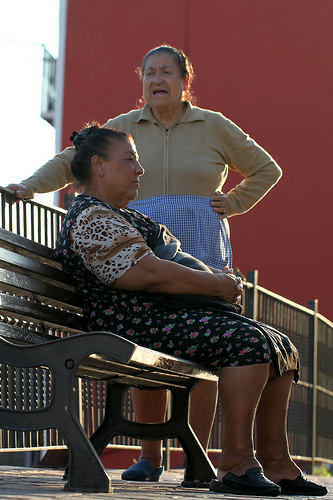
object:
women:
[54, 121, 327, 497]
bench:
[2, 229, 220, 494]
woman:
[5, 44, 284, 485]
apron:
[144, 213, 231, 269]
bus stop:
[2, 42, 331, 500]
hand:
[210, 188, 230, 222]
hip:
[202, 195, 231, 243]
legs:
[0, 373, 217, 500]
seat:
[28, 330, 217, 394]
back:
[0, 228, 86, 343]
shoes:
[208, 467, 280, 496]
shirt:
[69, 201, 153, 285]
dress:
[56, 193, 302, 384]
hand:
[2, 183, 34, 204]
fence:
[0, 186, 332, 468]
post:
[247, 269, 259, 322]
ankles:
[213, 445, 305, 481]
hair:
[67, 122, 133, 184]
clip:
[69, 131, 81, 145]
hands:
[217, 270, 236, 301]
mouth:
[152, 88, 170, 96]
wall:
[59, 0, 332, 470]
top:
[66, 115, 147, 212]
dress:
[18, 103, 286, 216]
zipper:
[159, 126, 171, 195]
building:
[53, 0, 332, 469]